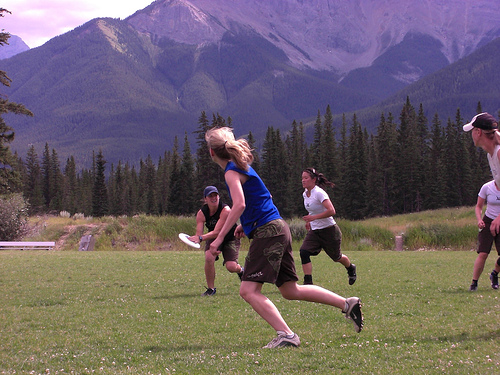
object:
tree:
[396, 95, 421, 210]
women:
[201, 125, 365, 353]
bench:
[0, 240, 57, 252]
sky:
[0, 0, 156, 50]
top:
[321, 103, 335, 128]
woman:
[185, 184, 244, 297]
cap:
[203, 184, 221, 196]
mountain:
[0, 16, 188, 181]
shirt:
[224, 160, 285, 241]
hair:
[204, 126, 256, 173]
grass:
[0, 248, 500, 375]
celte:
[11, 219, 109, 252]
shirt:
[303, 184, 337, 230]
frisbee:
[177, 231, 202, 250]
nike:
[304, 197, 316, 206]